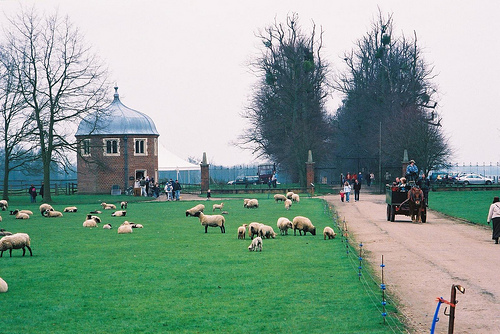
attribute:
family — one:
[335, 171, 364, 201]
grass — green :
[2, 196, 400, 331]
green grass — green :
[11, 260, 162, 331]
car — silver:
[453, 160, 493, 198]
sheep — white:
[192, 209, 233, 236]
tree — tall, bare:
[227, 8, 334, 184]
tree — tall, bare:
[321, 4, 454, 188]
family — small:
[337, 175, 362, 203]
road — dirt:
[317, 181, 484, 331]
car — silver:
[456, 172, 484, 185]